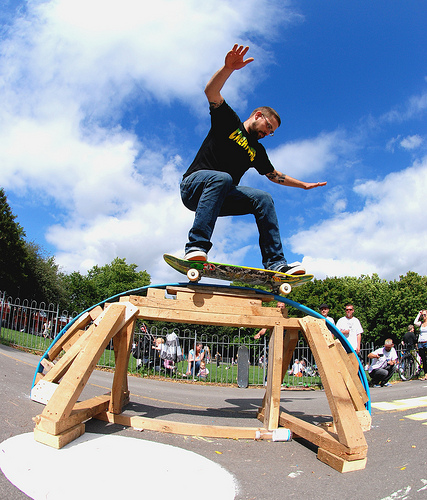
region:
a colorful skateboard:
[160, 253, 325, 293]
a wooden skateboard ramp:
[24, 273, 383, 474]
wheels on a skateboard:
[271, 279, 300, 298]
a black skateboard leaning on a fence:
[226, 336, 256, 389]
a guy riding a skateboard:
[160, 42, 333, 295]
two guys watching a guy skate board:
[314, 303, 374, 379]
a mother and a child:
[185, 341, 213, 380]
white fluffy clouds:
[23, 105, 165, 252]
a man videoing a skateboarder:
[365, 332, 398, 389]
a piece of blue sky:
[288, 14, 395, 107]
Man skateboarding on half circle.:
[156, 35, 332, 294]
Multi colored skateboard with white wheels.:
[151, 253, 312, 298]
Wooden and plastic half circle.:
[24, 275, 377, 479]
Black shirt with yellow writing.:
[174, 98, 276, 184]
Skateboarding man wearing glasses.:
[246, 102, 283, 144]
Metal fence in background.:
[0, 292, 420, 387]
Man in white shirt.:
[336, 302, 364, 356]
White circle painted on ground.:
[1, 425, 262, 498]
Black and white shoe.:
[269, 261, 308, 278]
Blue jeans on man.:
[178, 165, 306, 267]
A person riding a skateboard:
[160, 44, 327, 274]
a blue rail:
[30, 284, 372, 412]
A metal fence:
[0, 293, 425, 382]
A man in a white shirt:
[336, 300, 362, 353]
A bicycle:
[398, 343, 426, 381]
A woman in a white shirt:
[412, 309, 426, 376]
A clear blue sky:
[0, 0, 426, 281]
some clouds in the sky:
[0, 5, 423, 282]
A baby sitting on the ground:
[194, 361, 209, 378]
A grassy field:
[2, 324, 425, 385]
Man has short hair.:
[251, 102, 291, 127]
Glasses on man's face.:
[263, 111, 287, 151]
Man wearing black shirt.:
[210, 119, 258, 175]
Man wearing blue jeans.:
[180, 173, 286, 249]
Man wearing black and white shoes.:
[185, 244, 314, 277]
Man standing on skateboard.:
[183, 239, 321, 293]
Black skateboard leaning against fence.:
[226, 344, 257, 394]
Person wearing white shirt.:
[341, 314, 355, 339]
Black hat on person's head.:
[318, 297, 336, 308]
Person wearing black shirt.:
[402, 328, 422, 348]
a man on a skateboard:
[159, 44, 325, 295]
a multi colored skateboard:
[161, 252, 314, 298]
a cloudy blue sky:
[0, 1, 426, 288]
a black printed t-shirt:
[183, 100, 271, 179]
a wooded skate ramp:
[31, 278, 373, 470]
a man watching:
[335, 301, 362, 355]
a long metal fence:
[0, 289, 426, 387]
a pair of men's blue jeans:
[178, 172, 282, 261]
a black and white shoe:
[183, 247, 204, 259]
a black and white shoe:
[269, 261, 304, 274]